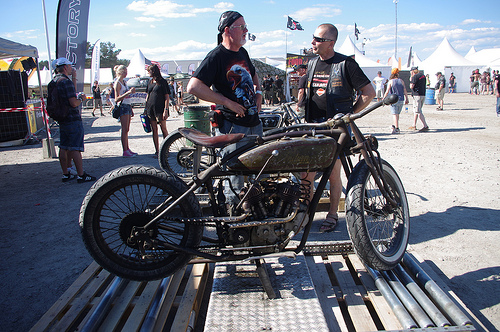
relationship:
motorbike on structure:
[78, 93, 412, 300] [30, 203, 493, 318]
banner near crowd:
[51, 2, 88, 102] [21, 38, 494, 128]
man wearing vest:
[297, 22, 376, 233] [302, 56, 349, 113]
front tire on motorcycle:
[341, 152, 413, 272] [75, 90, 412, 301]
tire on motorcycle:
[76, 167, 204, 282] [72, 94, 419, 279]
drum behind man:
[184, 104, 211, 146] [184, 12, 277, 129]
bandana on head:
[216, 8, 245, 34] [300, 18, 352, 62]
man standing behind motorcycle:
[297, 22, 376, 233] [75, 90, 412, 301]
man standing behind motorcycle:
[184, 10, 266, 208] [75, 90, 412, 301]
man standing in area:
[24, 46, 104, 188] [7, 80, 490, 330]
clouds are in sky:
[8, 5, 495, 64] [0, 3, 496, 63]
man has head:
[184, 10, 266, 208] [219, 8, 249, 48]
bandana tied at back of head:
[217, 10, 244, 47] [219, 8, 249, 48]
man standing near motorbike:
[189, 14, 277, 114] [78, 93, 412, 300]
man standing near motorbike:
[297, 22, 376, 233] [78, 93, 412, 300]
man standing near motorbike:
[143, 58, 173, 108] [78, 93, 412, 300]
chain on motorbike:
[151, 203, 296, 253] [78, 93, 412, 300]